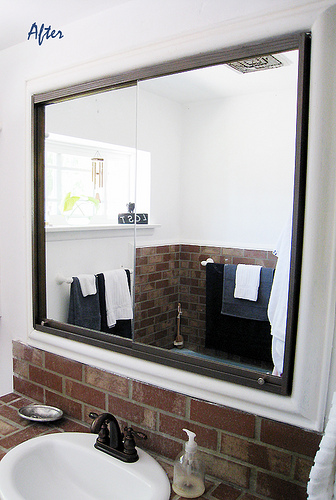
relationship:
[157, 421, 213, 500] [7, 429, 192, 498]
soap bottle by sink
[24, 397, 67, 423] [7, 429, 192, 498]
soap dish next to sink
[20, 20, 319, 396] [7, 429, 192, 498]
mirror above sink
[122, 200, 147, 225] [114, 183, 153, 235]
statue in corner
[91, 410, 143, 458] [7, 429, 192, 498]
faucet on sink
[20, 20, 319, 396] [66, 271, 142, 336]
mirror reflects towels